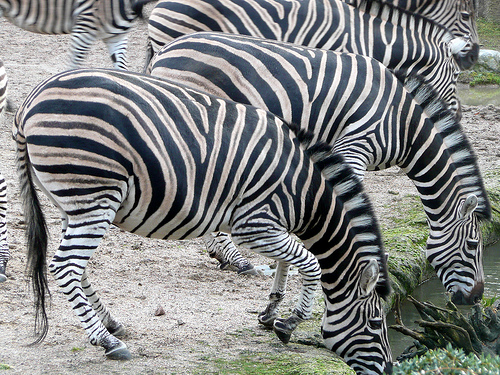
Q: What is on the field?
A: Zebras.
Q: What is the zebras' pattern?
A: Stripes.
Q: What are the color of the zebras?
A: Black and white.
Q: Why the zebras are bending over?
A: To ear.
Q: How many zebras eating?
A: Two.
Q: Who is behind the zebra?
A: No one.